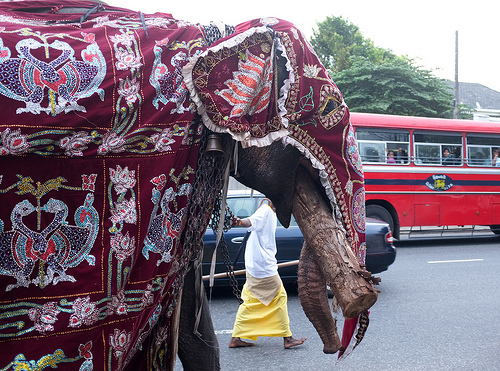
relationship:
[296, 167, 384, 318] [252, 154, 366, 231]
log in elephant mouth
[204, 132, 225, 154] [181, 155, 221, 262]
bell on chain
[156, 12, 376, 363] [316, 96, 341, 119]
elephant has eye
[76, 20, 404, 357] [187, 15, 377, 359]
elephant wearing cloth hood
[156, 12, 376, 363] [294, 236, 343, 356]
elephant carrying trunk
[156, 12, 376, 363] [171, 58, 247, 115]
elephant has cover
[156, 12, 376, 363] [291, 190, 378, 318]
elephant carrying log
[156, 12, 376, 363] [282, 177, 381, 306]
elephant has trunk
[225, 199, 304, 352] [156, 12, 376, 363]
man walking beside an elephant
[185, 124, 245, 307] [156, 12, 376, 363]
chains worn by elephant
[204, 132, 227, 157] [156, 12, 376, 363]
bell worn by elephant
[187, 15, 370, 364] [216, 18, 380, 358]
cloth hood covering elephant head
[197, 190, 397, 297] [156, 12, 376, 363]
car behind elephant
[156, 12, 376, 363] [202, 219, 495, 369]
elephant walking down street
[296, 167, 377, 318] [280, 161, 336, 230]
log in mouth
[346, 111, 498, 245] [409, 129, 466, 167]
bus has window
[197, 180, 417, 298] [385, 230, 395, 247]
car has tail light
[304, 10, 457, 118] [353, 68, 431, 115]
tree has leaves